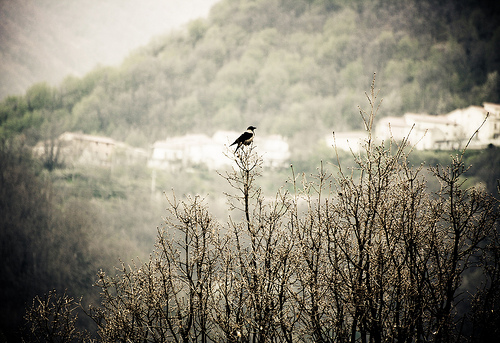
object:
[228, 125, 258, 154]
bird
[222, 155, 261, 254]
branch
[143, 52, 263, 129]
forest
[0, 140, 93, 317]
bushes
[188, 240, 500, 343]
bush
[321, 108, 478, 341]
branches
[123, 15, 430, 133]
area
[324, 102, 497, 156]
building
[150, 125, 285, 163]
building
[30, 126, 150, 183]
building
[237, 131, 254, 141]
bird wing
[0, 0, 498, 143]
trees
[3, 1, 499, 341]
hillside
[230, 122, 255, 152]
corvide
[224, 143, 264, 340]
branch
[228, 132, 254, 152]
black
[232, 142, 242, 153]
tail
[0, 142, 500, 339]
tree